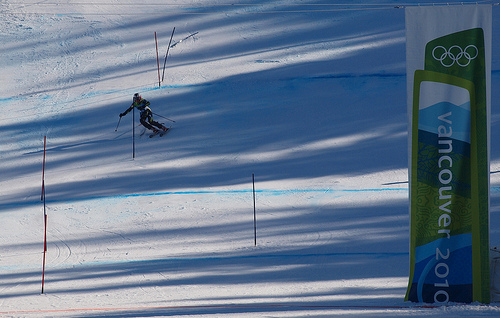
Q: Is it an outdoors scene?
A: Yes, it is outdoors.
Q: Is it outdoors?
A: Yes, it is outdoors.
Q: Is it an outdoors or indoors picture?
A: It is outdoors.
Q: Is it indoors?
A: No, it is outdoors.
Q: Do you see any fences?
A: No, there are no fences.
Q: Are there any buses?
A: No, there are no buses.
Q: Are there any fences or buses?
A: No, there are no buses or fences.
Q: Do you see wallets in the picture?
A: No, there are no wallets.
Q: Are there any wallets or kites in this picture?
A: No, there are no wallets or kites.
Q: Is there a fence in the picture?
A: No, there are no fences.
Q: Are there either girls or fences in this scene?
A: No, there are no fences or girls.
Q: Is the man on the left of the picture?
A: Yes, the man is on the left of the image.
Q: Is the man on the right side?
A: No, the man is on the left of the image.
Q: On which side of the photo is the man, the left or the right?
A: The man is on the left of the image.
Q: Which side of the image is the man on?
A: The man is on the left of the image.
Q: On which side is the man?
A: The man is on the left of the image.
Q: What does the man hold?
A: The man holds the pole.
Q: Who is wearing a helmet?
A: The man is wearing a helmet.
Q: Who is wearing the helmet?
A: The man is wearing a helmet.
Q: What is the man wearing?
A: The man is wearing a helmet.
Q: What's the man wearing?
A: The man is wearing a helmet.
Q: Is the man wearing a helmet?
A: Yes, the man is wearing a helmet.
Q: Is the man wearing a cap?
A: No, the man is wearing a helmet.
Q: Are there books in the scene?
A: No, there are no books.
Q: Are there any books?
A: No, there are no books.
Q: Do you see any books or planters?
A: No, there are no books or planters.